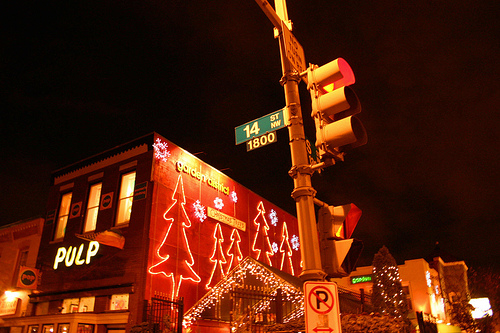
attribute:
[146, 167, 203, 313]
lights — christmas tree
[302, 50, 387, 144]
light — red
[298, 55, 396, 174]
light — yellow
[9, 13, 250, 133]
sky — dark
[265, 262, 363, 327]
sign — white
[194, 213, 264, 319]
tree — neon lit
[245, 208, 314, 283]
tree — neon lit